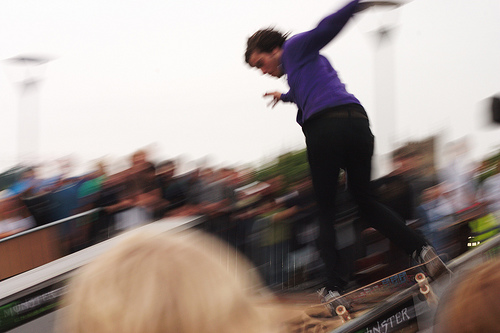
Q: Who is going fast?
A: A skateboarder.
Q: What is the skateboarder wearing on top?
A: A purple shirt.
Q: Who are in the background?
A: A crowd of onlookers.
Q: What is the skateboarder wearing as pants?
A: A pair of black jeans.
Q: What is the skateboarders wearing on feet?
A: Black and white sneakers.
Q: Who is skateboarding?
A: Guy in purple shirt.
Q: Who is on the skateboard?
A: Man wearing skinny pants.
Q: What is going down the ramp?
A: Skateboard.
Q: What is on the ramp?
A: Guy riding skateboard.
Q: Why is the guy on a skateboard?
A: He is riding on a ramp.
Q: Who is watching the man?
A: Some people.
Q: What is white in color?
A: The sky.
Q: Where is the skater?
A: Skatepark.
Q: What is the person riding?
A: A board.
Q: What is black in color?
A: Man's pants.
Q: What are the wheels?
A: White.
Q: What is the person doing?
A: Skateboarding.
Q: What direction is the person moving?
A: Downward.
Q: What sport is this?
A: Skating.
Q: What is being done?
A: Trick.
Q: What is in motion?
A: The man.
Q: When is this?
A: Daytime.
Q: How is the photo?
A: Blurry.